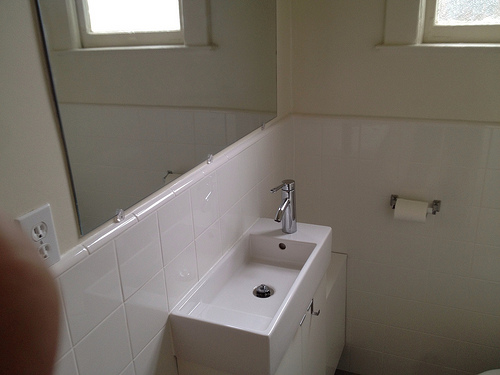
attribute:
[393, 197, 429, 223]
toilet paper — white, rolled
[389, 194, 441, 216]
mounted dispenser — chrome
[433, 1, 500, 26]
window — frosted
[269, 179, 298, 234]
faucet — chrome, silver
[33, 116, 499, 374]
wall tiles — white, ceramic, shiny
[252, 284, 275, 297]
drain — chrome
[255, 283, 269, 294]
stopper — chrome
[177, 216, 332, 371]
sink — white, porcelain, rectangle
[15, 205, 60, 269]
electrical outlet — doubled, white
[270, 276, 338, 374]
cabinet — white